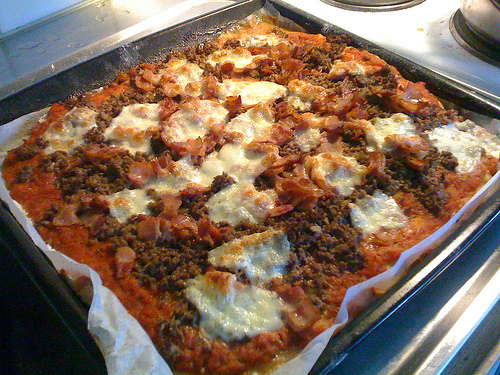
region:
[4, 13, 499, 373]
dish with entree inside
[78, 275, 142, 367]
lining paper under dish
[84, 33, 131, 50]
edge of dish with food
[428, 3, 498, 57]
other structure near dish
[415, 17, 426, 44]
splatter of food from dish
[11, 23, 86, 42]
top surface dish rests on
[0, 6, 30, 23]
blue backdrop against dish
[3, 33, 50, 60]
patch of liquid on surface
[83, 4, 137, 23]
additional patch of liquid on surface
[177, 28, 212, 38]
browned spot on dish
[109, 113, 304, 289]
the cheese is melted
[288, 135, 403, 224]
the cheese is melted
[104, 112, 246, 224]
the cheese is melted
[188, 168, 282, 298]
the cheese is melted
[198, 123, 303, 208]
the cheese is melted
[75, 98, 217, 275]
the meat is grounded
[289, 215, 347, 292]
the meat is grounded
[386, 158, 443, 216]
the meat is grounded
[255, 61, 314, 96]
the meat is grounded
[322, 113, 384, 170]
the meat is grounded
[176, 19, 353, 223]
Food on the plate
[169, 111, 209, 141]
Sauce in the food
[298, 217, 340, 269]
Meat on the plate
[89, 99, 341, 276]
Food on the tray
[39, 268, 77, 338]
A tray in the photo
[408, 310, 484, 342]
A table in the photo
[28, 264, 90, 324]
A black tray in the photo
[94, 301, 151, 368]
A wrapper in the tray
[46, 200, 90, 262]
Red sauce in the food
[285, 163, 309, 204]
Onions in the food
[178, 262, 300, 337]
cheese on top of food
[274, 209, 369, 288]
meat is next to cheese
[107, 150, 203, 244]
bacon is on the meat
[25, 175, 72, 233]
red sauce around the edges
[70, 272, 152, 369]
white liner paper around the dish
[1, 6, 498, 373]
food is in a dish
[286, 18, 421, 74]
dish is on the stove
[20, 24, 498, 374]
food has not been cut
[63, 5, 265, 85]
food is burnt along the edge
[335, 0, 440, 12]
burner on the stove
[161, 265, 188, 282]
topping in the pasta mix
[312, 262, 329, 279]
topping in the pasta mix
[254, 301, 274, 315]
topping in the pasta mix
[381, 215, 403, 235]
topping in the pasta mix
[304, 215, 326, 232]
topping in the pasta mix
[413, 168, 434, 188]
topping in the pasta mix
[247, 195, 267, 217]
topping in the pasta mix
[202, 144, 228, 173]
topping in the pasta mix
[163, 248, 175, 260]
topping in the pasta mix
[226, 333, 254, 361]
topping in the pasta mix